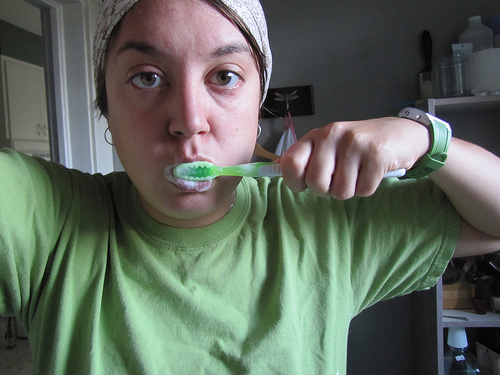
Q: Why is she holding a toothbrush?
A: To brush her teeth.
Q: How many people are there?
A: One.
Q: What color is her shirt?
A: Green.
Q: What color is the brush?
A: Green and white.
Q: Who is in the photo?
A: A lady.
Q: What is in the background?
A: A wall.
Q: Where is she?
A: In a bathroom.